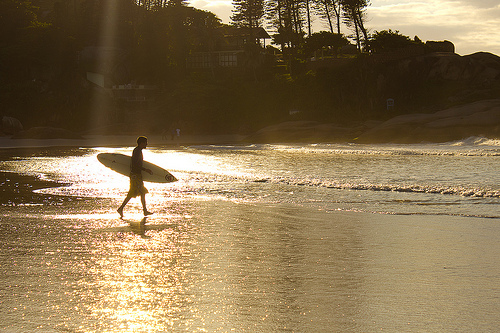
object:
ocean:
[203, 147, 500, 331]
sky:
[387, 1, 500, 38]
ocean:
[1, 232, 182, 332]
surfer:
[116, 134, 153, 219]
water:
[208, 143, 489, 218]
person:
[113, 136, 157, 219]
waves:
[188, 151, 492, 198]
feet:
[115, 209, 127, 220]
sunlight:
[298, 141, 419, 158]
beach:
[4, 219, 498, 331]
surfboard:
[92, 152, 181, 185]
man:
[115, 135, 159, 216]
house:
[211, 22, 272, 72]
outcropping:
[371, 21, 461, 75]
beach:
[0, 128, 500, 213]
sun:
[157, 149, 224, 171]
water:
[13, 247, 242, 333]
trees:
[322, 1, 343, 36]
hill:
[367, 4, 498, 107]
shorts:
[124, 183, 147, 199]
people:
[158, 125, 174, 140]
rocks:
[11, 124, 86, 139]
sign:
[385, 98, 395, 111]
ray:
[59, 153, 95, 186]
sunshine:
[61, 157, 87, 181]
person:
[175, 126, 184, 138]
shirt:
[175, 127, 181, 134]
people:
[169, 128, 176, 142]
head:
[134, 136, 150, 148]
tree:
[346, 0, 367, 48]